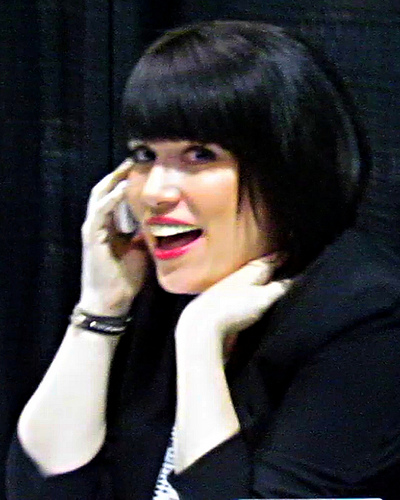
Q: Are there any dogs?
A: No, there are no dogs.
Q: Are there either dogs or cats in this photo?
A: No, there are no dogs or cats.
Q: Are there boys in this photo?
A: No, there are no boys.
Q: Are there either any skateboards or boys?
A: No, there are no boys or skateboards.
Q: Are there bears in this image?
A: No, there are no bears.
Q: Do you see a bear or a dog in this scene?
A: No, there are no bears or dogs.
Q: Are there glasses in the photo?
A: No, there are no glasses.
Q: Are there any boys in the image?
A: No, there are no boys.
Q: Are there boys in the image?
A: No, there are no boys.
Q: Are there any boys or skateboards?
A: No, there are no boys or skateboards.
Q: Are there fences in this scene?
A: No, there are no fences.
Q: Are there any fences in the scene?
A: No, there are no fences.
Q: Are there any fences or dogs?
A: No, there are no fences or dogs.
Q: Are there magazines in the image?
A: No, there are no magazines.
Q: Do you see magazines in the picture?
A: No, there are no magazines.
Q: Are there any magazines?
A: No, there are no magazines.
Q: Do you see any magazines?
A: No, there are no magazines.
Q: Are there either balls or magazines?
A: No, there are no magazines or balls.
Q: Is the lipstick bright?
A: Yes, the lipstick is bright.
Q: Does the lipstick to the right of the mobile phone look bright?
A: Yes, the lipstick is bright.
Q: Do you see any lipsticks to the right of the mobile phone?
A: Yes, there is a lipstick to the right of the mobile phone.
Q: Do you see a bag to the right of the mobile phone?
A: No, there is a lipstick to the right of the mobile phone.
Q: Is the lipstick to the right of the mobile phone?
A: Yes, the lipstick is to the right of the mobile phone.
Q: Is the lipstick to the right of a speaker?
A: No, the lipstick is to the right of the mobile phone.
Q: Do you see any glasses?
A: No, there are no glasses.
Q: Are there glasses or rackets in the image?
A: No, there are no glasses or rackets.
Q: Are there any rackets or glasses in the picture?
A: No, there are no glasses or rackets.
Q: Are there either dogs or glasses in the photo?
A: No, there are no dogs or glasses.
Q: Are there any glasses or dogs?
A: No, there are no dogs or glasses.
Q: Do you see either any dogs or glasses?
A: No, there are no dogs or glasses.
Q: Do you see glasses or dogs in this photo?
A: No, there are no dogs or glasses.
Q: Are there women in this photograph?
A: Yes, there is a woman.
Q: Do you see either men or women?
A: Yes, there is a woman.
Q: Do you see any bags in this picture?
A: No, there are no bags.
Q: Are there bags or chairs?
A: No, there are no bags or chairs.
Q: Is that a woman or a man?
A: That is a woman.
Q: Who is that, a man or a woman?
A: That is a woman.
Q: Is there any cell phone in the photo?
A: Yes, there is a cell phone.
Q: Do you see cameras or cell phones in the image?
A: Yes, there is a cell phone.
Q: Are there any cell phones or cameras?
A: Yes, there is a cell phone.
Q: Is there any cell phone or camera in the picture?
A: Yes, there is a cell phone.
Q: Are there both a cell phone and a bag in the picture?
A: No, there is a cell phone but no bags.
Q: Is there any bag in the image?
A: No, there are no bags.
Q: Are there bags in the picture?
A: No, there are no bags.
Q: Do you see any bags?
A: No, there are no bags.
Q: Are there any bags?
A: No, there are no bags.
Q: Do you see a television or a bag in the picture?
A: No, there are no bags or televisions.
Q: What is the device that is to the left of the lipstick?
A: The device is a cell phone.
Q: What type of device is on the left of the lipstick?
A: The device is a cell phone.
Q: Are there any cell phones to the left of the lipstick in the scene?
A: Yes, there is a cell phone to the left of the lipstick.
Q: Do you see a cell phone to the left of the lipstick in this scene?
A: Yes, there is a cell phone to the left of the lipstick.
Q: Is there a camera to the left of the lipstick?
A: No, there is a cell phone to the left of the lipstick.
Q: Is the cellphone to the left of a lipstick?
A: Yes, the cellphone is to the left of a lipstick.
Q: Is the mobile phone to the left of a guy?
A: No, the mobile phone is to the left of a lipstick.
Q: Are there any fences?
A: No, there are no fences.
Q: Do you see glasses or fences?
A: No, there are no fences or glasses.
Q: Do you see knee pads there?
A: No, there are no knee pads.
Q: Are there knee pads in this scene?
A: No, there are no knee pads.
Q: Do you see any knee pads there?
A: No, there are no knee pads.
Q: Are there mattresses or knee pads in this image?
A: No, there are no knee pads or mattresses.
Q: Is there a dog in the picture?
A: No, there are no dogs.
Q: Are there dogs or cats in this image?
A: No, there are no dogs or cats.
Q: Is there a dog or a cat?
A: No, there are no dogs or cats.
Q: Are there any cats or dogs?
A: No, there are no dogs or cats.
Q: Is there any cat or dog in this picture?
A: No, there are no dogs or cats.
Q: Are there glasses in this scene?
A: No, there are no glasses.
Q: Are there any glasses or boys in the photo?
A: No, there are no glasses or boys.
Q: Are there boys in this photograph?
A: No, there are no boys.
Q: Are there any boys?
A: No, there are no boys.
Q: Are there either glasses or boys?
A: No, there are no boys or glasses.